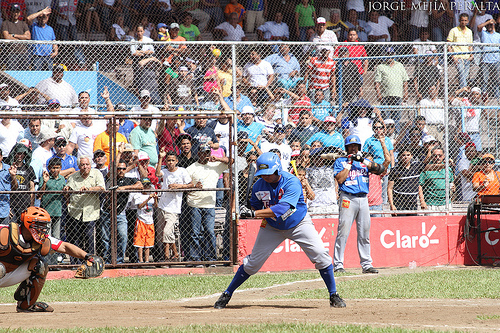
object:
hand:
[156, 147, 169, 158]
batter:
[215, 152, 347, 308]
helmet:
[256, 151, 282, 179]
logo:
[253, 189, 273, 205]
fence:
[1, 40, 498, 266]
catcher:
[0, 206, 106, 312]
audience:
[4, 6, 487, 267]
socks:
[318, 263, 338, 295]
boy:
[154, 147, 195, 266]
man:
[124, 152, 163, 267]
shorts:
[136, 218, 156, 247]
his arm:
[103, 98, 115, 118]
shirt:
[468, 170, 500, 198]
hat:
[158, 22, 169, 27]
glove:
[75, 254, 108, 279]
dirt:
[9, 267, 499, 333]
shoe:
[329, 293, 346, 308]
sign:
[343, 200, 350, 208]